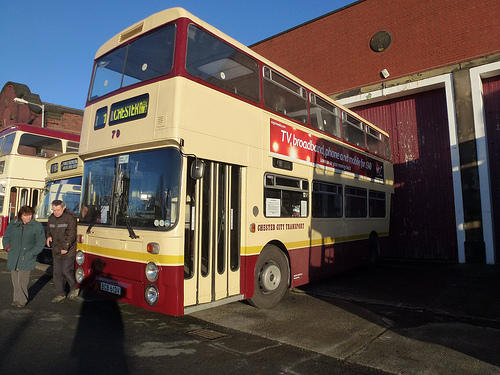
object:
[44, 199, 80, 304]
man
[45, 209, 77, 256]
coat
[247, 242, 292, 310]
wheel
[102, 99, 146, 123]
display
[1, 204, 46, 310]
people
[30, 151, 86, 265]
buses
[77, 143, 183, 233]
window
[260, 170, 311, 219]
window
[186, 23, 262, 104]
window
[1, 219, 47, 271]
coat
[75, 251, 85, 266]
light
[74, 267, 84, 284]
light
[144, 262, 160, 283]
light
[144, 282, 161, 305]
light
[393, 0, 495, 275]
building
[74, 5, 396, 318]
bus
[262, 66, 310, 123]
window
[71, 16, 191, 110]
windshield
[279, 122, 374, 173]
sign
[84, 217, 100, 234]
windshield wipers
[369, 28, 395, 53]
circle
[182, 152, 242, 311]
doors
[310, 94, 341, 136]
window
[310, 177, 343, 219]
window